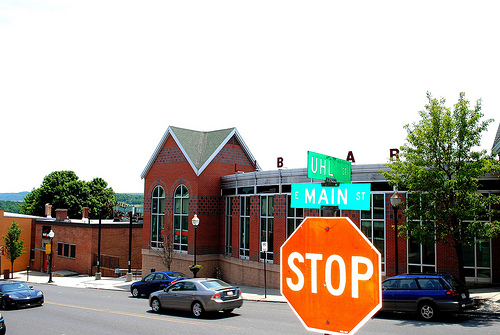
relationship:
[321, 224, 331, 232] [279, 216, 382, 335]
bolt on sign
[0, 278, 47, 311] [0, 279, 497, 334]
corvette driving down street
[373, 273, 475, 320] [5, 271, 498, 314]
car parked next to sidewalk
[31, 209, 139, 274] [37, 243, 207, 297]
building on sidewalk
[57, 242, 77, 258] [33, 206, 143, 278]
three windows on side of brick building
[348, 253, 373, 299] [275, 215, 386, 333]
letter on sign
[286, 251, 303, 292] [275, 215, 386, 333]
white letter on sign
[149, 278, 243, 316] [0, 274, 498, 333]
car on street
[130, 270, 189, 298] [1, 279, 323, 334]
car on street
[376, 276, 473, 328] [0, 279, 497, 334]
car on street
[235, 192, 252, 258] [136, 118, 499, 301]
window of building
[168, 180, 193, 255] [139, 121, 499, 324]
window of building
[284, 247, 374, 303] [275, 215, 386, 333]
letters of sign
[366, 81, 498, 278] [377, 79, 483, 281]
leaves of tree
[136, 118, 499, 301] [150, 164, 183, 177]
building made of red brick.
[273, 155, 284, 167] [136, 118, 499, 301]
b on top of building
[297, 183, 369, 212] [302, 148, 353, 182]
main street on street sign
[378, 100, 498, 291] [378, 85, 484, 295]
leaves on tree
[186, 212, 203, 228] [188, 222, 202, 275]
light on pole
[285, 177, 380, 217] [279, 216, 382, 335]
street sign over sign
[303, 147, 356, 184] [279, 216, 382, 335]
street sign over sign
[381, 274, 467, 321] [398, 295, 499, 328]
car parked in shade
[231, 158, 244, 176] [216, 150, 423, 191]
letter on roof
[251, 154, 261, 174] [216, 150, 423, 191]
letter on roof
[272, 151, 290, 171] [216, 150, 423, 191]
letter on roof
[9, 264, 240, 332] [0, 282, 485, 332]
three cars on street